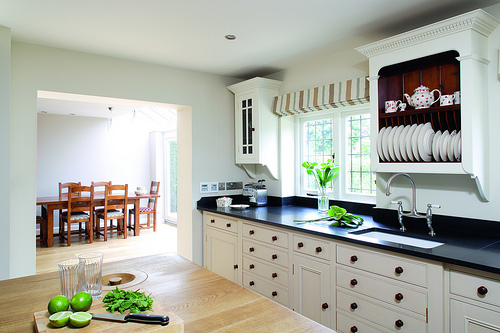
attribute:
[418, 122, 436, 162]
plate — white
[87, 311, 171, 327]
knife — black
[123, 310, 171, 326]
handle — black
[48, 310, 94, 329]
lime — sliced, cut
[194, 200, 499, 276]
counter top — black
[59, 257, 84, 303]
glass — empty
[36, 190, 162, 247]
table — long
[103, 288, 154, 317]
herbs — green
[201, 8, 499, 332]
cabinet — white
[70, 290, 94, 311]
lime — green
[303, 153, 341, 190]
flower — green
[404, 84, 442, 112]
teapot — white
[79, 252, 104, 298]
cup — glass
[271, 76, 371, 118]
valance — white